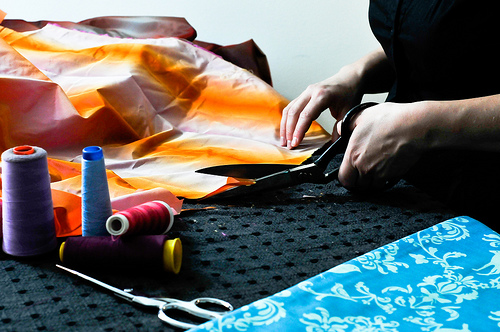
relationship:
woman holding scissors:
[280, 0, 500, 192] [194, 100, 380, 205]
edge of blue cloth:
[173, 205, 497, 327] [184, 216, 500, 331]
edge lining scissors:
[195, 170, 260, 180] [194, 100, 380, 205]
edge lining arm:
[380, 90, 485, 106] [333, 91, 481, 198]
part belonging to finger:
[300, 94, 321, 122] [290, 96, 327, 148]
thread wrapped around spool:
[110, 198, 170, 238] [103, 199, 175, 236]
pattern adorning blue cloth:
[183, 213, 484, 329] [184, 216, 500, 331]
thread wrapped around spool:
[63, 232, 169, 274] [56, 233, 184, 273]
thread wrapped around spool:
[4, 142, 57, 258] [81, 144, 112, 238]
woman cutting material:
[280, 0, 500, 192] [0, 23, 338, 239]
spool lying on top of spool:
[103, 199, 175, 236] [57, 230, 183, 276]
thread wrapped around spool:
[4, 142, 57, 258] [10, 143, 36, 154]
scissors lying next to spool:
[55, 261, 236, 329] [56, 233, 184, 273]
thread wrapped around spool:
[4, 142, 57, 258] [2, 143, 61, 260]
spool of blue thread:
[79, 147, 110, 161] [66, 140, 143, 268]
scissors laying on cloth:
[49, 259, 249, 329] [17, 177, 268, 329]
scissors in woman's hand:
[224, 95, 392, 206] [330, 99, 432, 192]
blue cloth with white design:
[179, 210, 498, 328] [344, 256, 468, 318]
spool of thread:
[55, 237, 189, 275] [3, 126, 201, 286]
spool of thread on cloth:
[55, 237, 189, 275] [4, 123, 217, 236]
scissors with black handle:
[193, 101, 380, 205] [321, 92, 419, 203]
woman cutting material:
[280, 0, 500, 192] [0, 14, 345, 226]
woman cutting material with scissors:
[280, 0, 500, 192] [218, 90, 430, 216]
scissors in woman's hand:
[193, 101, 380, 205] [330, 90, 435, 222]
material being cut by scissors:
[80, 36, 278, 221] [175, 71, 427, 220]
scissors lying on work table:
[55, 261, 236, 329] [4, 142, 496, 324]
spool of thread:
[55, 232, 189, 285] [63, 232, 193, 275]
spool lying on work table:
[55, 232, 189, 285] [4, 142, 496, 324]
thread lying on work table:
[63, 232, 193, 275] [4, 142, 496, 324]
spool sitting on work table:
[5, 136, 60, 262] [4, 100, 498, 326]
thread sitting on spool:
[4, 142, 58, 267] [5, 136, 60, 262]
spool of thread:
[5, 136, 60, 262] [4, 142, 58, 267]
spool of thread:
[76, 148, 135, 248] [4, 142, 57, 258]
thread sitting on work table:
[4, 142, 57, 258] [3, 130, 453, 324]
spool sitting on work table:
[76, 148, 135, 248] [3, 130, 453, 324]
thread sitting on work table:
[110, 198, 170, 238] [6, 160, 492, 321]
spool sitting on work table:
[103, 199, 193, 248] [6, 160, 492, 321]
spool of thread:
[103, 199, 193, 248] [110, 198, 170, 238]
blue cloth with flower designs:
[184, 216, 500, 331] [308, 251, 490, 329]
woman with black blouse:
[352, 0, 495, 229] [363, 3, 498, 215]